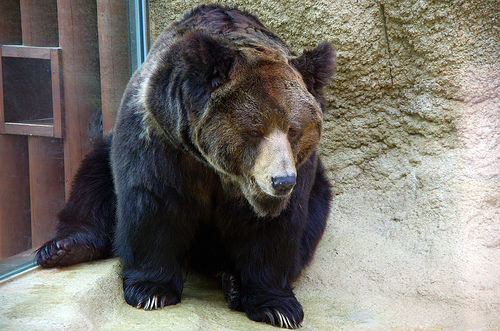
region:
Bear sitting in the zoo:
[23, 10, 481, 303]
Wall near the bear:
[393, 31, 483, 236]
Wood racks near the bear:
[28, 13, 63, 183]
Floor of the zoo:
[14, 290, 84, 325]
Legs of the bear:
[72, 233, 299, 328]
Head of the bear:
[171, 35, 353, 237]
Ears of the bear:
[173, 34, 363, 71]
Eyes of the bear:
[243, 108, 310, 139]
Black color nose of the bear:
[267, 164, 312, 199]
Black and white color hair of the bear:
[121, 97, 161, 247]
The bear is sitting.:
[38, 17, 352, 330]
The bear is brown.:
[42, 14, 354, 324]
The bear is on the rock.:
[39, 10, 374, 325]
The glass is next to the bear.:
[0, 2, 156, 282]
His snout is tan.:
[240, 128, 293, 216]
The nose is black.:
[268, 169, 297, 194]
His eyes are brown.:
[229, 113, 300, 148]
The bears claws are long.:
[125, 278, 182, 316]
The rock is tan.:
[146, 1, 497, 296]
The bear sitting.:
[38, 3, 360, 330]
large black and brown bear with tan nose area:
[25, 4, 357, 326]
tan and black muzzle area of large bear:
[245, 129, 300, 219]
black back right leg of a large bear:
[34, 129, 111, 271]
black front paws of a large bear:
[116, 269, 313, 329]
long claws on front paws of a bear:
[139, 297, 303, 330]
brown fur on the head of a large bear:
[201, 66, 327, 168]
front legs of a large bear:
[113, 146, 306, 329]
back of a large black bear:
[158, 0, 291, 57]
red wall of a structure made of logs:
[1, 1, 124, 232]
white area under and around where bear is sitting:
[6, 234, 472, 327]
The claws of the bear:
[141, 295, 164, 309]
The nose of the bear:
[272, 171, 295, 193]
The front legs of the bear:
[116, 174, 299, 326]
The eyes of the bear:
[240, 121, 300, 141]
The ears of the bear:
[181, 30, 336, 88]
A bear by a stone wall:
[37, 4, 334, 326]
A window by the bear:
[0, 0, 140, 279]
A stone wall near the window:
[146, 3, 498, 312]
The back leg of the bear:
[41, 136, 126, 256]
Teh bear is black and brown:
[38, 10, 334, 327]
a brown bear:
[55, 8, 337, 326]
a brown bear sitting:
[66, 6, 316, 326]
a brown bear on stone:
[61, 15, 332, 328]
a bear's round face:
[206, 80, 311, 205]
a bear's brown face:
[196, 65, 319, 215]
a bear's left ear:
[295, 40, 335, 88]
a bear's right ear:
[181, 35, 231, 81]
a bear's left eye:
[285, 123, 297, 138]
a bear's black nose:
[270, 173, 300, 193]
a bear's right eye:
[248, 128, 264, 138]